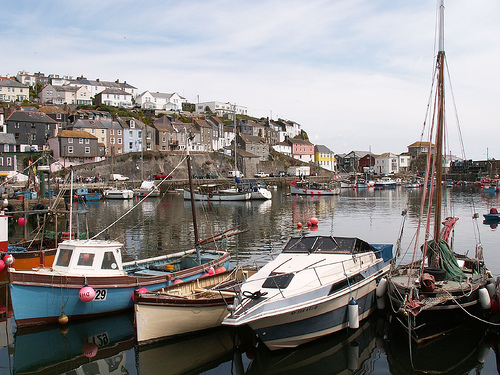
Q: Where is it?
A: This is at the harbor.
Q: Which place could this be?
A: It is a harbor.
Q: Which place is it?
A: It is a harbor.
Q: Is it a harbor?
A: Yes, it is a harbor.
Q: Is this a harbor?
A: Yes, it is a harbor.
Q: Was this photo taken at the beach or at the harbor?
A: It was taken at the harbor.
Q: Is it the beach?
A: No, it is the harbor.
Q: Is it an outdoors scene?
A: Yes, it is outdoors.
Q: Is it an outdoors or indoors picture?
A: It is outdoors.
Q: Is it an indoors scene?
A: No, it is outdoors.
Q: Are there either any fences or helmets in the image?
A: No, there are no fences or helmets.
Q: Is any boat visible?
A: Yes, there is a boat.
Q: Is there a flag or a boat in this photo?
A: Yes, there is a boat.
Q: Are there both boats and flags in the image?
A: No, there is a boat but no flags.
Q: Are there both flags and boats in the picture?
A: No, there is a boat but no flags.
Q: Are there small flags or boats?
A: Yes, there is a small boat.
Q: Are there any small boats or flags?
A: Yes, there is a small boat.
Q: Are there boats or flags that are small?
A: Yes, the boat is small.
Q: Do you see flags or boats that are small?
A: Yes, the boat is small.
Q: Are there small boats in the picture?
A: Yes, there is a small boat.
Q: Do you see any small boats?
A: Yes, there is a small boat.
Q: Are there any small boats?
A: Yes, there is a small boat.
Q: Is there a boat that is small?
A: Yes, there is a boat that is small.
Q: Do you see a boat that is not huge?
A: Yes, there is a small boat.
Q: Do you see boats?
A: Yes, there is a boat.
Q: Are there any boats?
A: Yes, there is a boat.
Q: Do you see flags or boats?
A: Yes, there is a boat.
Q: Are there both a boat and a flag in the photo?
A: No, there is a boat but no flags.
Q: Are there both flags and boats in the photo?
A: No, there is a boat but no flags.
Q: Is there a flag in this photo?
A: No, there are no flags.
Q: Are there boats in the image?
A: Yes, there is a boat.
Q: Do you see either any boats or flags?
A: Yes, there is a boat.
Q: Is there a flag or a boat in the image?
A: Yes, there is a boat.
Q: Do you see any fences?
A: No, there are no fences.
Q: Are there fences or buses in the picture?
A: No, there are no fences or buses.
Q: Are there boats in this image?
A: Yes, there is a boat.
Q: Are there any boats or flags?
A: Yes, there is a boat.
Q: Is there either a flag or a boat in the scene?
A: Yes, there is a boat.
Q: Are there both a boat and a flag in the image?
A: No, there is a boat but no flags.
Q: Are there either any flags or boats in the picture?
A: Yes, there is a boat.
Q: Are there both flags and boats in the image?
A: No, there is a boat but no flags.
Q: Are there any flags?
A: No, there are no flags.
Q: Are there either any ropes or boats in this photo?
A: Yes, there is a boat.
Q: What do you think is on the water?
A: The boat is on the water.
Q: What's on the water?
A: The boat is on the water.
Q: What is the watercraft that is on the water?
A: The watercraft is a boat.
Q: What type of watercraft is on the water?
A: The watercraft is a boat.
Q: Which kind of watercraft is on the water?
A: The watercraft is a boat.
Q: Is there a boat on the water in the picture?
A: Yes, there is a boat on the water.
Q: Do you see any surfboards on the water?
A: No, there is a boat on the water.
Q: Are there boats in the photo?
A: Yes, there is a boat.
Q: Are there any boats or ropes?
A: Yes, there is a boat.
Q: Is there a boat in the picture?
A: Yes, there is a boat.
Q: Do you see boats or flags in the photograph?
A: Yes, there is a boat.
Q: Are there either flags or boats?
A: Yes, there is a boat.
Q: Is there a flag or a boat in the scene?
A: Yes, there is a boat.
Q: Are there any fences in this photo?
A: No, there are no fences.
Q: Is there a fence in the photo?
A: No, there are no fences.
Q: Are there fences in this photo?
A: No, there are no fences.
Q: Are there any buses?
A: No, there are no buses.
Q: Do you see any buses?
A: No, there are no buses.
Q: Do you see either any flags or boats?
A: Yes, there is a boat.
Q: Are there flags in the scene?
A: No, there are no flags.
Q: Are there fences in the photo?
A: No, there are no fences.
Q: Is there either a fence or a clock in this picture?
A: No, there are no fences or clocks.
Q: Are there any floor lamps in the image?
A: No, there are no floor lamps.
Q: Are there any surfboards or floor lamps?
A: No, there are no floor lamps or surfboards.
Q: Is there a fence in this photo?
A: No, there are no fences.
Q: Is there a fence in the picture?
A: No, there are no fences.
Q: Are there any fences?
A: No, there are no fences.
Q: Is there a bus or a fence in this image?
A: No, there are no fences or buses.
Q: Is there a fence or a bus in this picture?
A: No, there are no fences or buses.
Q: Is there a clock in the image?
A: No, there are no clocks.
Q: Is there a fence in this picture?
A: No, there are no fences.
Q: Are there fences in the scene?
A: No, there are no fences.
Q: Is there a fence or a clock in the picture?
A: No, there are no fences or clocks.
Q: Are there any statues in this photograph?
A: No, there are no statues.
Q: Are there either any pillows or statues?
A: No, there are no statues or pillows.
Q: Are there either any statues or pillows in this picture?
A: No, there are no statues or pillows.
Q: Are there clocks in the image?
A: No, there are no clocks.